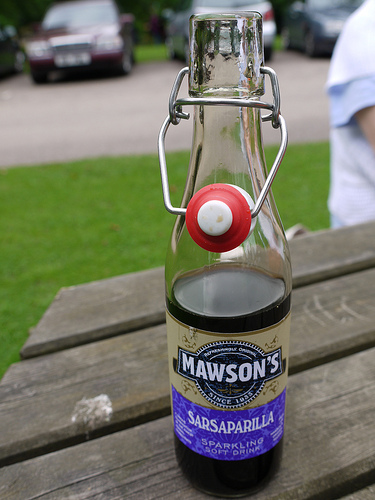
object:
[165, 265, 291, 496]
liquid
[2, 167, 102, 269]
grass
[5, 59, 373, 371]
ground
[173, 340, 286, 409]
label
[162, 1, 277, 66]
car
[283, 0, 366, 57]
car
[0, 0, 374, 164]
background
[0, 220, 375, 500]
table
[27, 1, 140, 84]
stew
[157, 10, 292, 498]
beverage bottle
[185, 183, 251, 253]
cover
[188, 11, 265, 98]
mouth holder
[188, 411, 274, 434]
word sarsaparilla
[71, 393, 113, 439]
stain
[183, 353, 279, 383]
mawson's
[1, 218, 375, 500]
picnic table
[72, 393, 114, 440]
bird dropping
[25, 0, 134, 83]
car